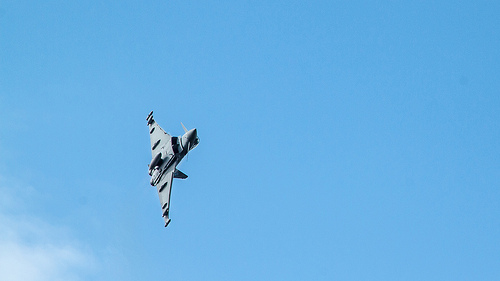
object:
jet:
[143, 104, 198, 228]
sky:
[1, 0, 499, 281]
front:
[180, 128, 200, 153]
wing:
[142, 111, 171, 138]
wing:
[157, 181, 184, 229]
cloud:
[8, 182, 64, 279]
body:
[147, 136, 183, 174]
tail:
[146, 160, 163, 186]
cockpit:
[185, 138, 201, 149]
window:
[184, 139, 198, 150]